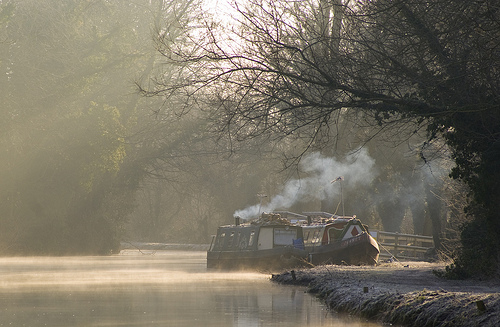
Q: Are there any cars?
A: No, there are no cars.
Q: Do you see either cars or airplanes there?
A: No, there are no cars or airplanes.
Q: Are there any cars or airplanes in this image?
A: No, there are no cars or airplanes.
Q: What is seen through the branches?
A: The sky is seen through the branches.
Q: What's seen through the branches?
A: The sky is seen through the branches.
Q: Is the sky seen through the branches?
A: Yes, the sky is seen through the branches.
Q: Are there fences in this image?
A: Yes, there is a fence.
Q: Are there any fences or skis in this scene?
A: Yes, there is a fence.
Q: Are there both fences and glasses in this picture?
A: No, there is a fence but no glasses.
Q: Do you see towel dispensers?
A: No, there are no towel dispensers.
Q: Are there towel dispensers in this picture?
A: No, there are no towel dispensers.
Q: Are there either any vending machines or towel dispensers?
A: No, there are no towel dispensers or vending machines.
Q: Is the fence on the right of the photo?
A: Yes, the fence is on the right of the image.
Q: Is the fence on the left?
A: No, the fence is on the right of the image.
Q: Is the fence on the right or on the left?
A: The fence is on the right of the image.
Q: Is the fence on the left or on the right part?
A: The fence is on the right of the image.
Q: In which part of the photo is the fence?
A: The fence is on the right of the image.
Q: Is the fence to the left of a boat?
A: No, the fence is to the right of a boat.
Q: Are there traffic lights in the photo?
A: No, there are no traffic lights.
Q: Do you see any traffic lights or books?
A: No, there are no traffic lights or books.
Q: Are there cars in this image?
A: No, there are no cars.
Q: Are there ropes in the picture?
A: No, there are no ropes.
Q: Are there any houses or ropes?
A: No, there are no ropes or houses.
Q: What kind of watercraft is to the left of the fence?
A: The watercraft is boats.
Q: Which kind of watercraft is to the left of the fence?
A: The watercraft is boats.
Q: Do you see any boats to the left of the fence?
A: Yes, there are boats to the left of the fence.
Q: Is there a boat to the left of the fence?
A: Yes, there are boats to the left of the fence.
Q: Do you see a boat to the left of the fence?
A: Yes, there are boats to the left of the fence.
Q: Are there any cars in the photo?
A: No, there are no cars.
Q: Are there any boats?
A: Yes, there is a boat.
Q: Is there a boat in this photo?
A: Yes, there is a boat.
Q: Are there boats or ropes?
A: Yes, there is a boat.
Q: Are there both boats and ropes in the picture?
A: No, there is a boat but no ropes.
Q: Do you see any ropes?
A: No, there are no ropes.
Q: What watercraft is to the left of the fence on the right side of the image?
A: The watercraft is a boat.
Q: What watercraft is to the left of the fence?
A: The watercraft is a boat.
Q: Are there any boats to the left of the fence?
A: Yes, there is a boat to the left of the fence.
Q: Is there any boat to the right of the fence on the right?
A: No, the boat is to the left of the fence.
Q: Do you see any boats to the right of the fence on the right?
A: No, the boat is to the left of the fence.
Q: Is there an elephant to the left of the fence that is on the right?
A: No, there is a boat to the left of the fence.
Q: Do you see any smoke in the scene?
A: Yes, there is smoke.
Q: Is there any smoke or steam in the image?
A: Yes, there is smoke.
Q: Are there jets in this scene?
A: No, there are no jets.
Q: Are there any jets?
A: No, there are no jets.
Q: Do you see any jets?
A: No, there are no jets.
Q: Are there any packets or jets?
A: No, there are no jets or packets.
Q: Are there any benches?
A: No, there are no benches.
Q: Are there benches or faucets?
A: No, there are no benches or faucets.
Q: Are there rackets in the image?
A: No, there are no rackets.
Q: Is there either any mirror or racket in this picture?
A: No, there are no rackets or mirrors.